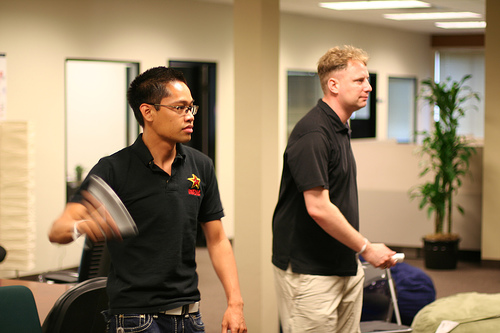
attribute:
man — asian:
[44, 61, 254, 330]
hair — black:
[122, 65, 188, 130]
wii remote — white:
[82, 166, 143, 240]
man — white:
[266, 39, 407, 332]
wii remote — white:
[378, 243, 409, 272]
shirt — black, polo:
[68, 131, 227, 323]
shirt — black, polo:
[267, 97, 363, 279]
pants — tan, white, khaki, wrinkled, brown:
[270, 255, 368, 332]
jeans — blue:
[95, 300, 208, 333]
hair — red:
[314, 42, 370, 99]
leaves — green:
[408, 72, 487, 217]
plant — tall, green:
[411, 72, 485, 274]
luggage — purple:
[388, 258, 438, 326]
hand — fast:
[75, 189, 123, 246]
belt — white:
[159, 296, 204, 318]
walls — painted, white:
[0, 1, 499, 282]